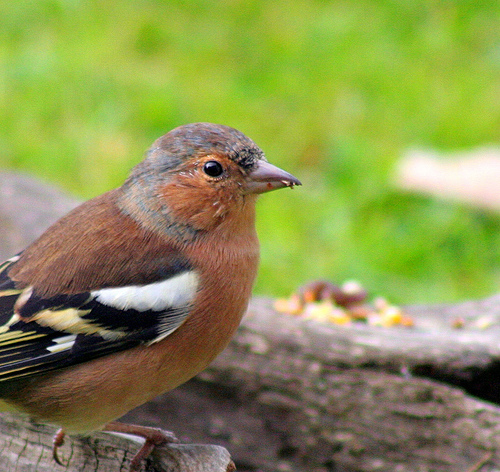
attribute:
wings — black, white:
[38, 259, 201, 384]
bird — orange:
[98, 88, 323, 380]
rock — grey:
[2, 414, 233, 470]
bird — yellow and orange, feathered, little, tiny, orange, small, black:
[0, 121, 301, 469]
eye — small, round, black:
[201, 157, 223, 178]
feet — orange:
[51, 423, 176, 470]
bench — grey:
[1, 406, 237, 470]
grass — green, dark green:
[0, 5, 497, 305]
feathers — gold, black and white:
[0, 251, 201, 389]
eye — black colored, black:
[204, 157, 222, 177]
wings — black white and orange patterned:
[0, 252, 199, 393]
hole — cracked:
[331, 353, 499, 413]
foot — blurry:
[390, 138, 499, 218]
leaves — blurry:
[2, 2, 499, 307]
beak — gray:
[253, 157, 298, 189]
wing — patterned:
[0, 259, 200, 397]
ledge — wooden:
[0, 170, 496, 470]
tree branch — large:
[2, 170, 498, 470]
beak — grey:
[250, 160, 300, 190]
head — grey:
[151, 122, 305, 227]